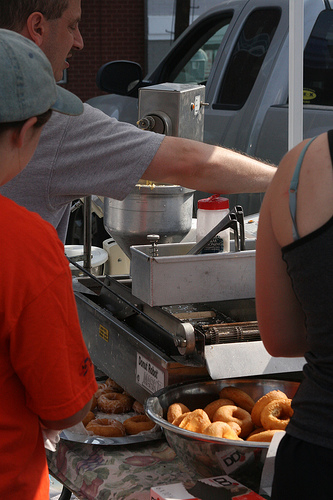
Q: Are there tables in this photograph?
A: Yes, there is a table.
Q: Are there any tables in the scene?
A: Yes, there is a table.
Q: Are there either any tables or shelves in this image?
A: Yes, there is a table.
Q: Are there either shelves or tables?
A: Yes, there is a table.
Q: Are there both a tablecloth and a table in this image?
A: Yes, there are both a table and a tablecloth.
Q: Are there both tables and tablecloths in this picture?
A: Yes, there are both a table and a tablecloth.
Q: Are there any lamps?
A: No, there are no lamps.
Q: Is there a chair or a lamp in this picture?
A: No, there are no lamps or chairs.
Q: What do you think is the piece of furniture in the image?
A: The piece of furniture is a table.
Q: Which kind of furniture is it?
A: The piece of furniture is a table.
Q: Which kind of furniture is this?
A: This is a table.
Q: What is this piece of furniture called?
A: This is a table.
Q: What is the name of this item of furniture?
A: This is a table.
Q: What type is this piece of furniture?
A: This is a table.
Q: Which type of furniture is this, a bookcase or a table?
A: This is a table.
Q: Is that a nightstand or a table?
A: That is a table.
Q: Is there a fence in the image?
A: No, there are no fences.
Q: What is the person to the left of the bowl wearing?
A: The person is wearing a shirt.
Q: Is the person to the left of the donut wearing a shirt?
A: Yes, the person is wearing a shirt.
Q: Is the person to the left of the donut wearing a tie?
A: No, the person is wearing a shirt.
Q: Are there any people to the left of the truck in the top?
A: Yes, there is a person to the left of the truck.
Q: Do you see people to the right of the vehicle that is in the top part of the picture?
A: No, the person is to the left of the truck.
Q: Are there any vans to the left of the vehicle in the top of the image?
A: No, there is a person to the left of the truck.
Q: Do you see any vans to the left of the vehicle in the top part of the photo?
A: No, there is a person to the left of the truck.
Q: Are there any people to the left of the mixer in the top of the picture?
A: Yes, there is a person to the left of the mixer.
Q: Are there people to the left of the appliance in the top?
A: Yes, there is a person to the left of the mixer.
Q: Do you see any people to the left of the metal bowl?
A: Yes, there is a person to the left of the bowl.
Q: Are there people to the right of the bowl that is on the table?
A: No, the person is to the left of the bowl.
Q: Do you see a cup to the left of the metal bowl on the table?
A: No, there is a person to the left of the bowl.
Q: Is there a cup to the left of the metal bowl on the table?
A: No, there is a person to the left of the bowl.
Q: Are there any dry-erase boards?
A: No, there are no dry-erase boards.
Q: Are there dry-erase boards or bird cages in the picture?
A: No, there are no dry-erase boards or bird cages.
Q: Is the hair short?
A: Yes, the hair is short.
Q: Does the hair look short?
A: Yes, the hair is short.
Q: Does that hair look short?
A: Yes, the hair is short.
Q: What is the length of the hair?
A: The hair is short.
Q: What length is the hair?
A: The hair is short.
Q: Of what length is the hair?
A: The hair is short.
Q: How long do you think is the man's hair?
A: The hair is short.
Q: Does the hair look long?
A: No, the hair is short.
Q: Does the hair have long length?
A: No, the hair is short.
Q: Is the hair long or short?
A: The hair is short.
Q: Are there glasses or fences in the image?
A: No, there are no fences or glasses.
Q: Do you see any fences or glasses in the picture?
A: No, there are no fences or glasses.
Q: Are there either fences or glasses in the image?
A: No, there are no fences or glasses.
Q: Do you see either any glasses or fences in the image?
A: No, there are no fences or glasses.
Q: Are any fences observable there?
A: No, there are no fences.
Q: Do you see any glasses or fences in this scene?
A: No, there are no fences or glasses.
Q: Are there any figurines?
A: No, there are no figurines.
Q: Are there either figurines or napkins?
A: No, there are no figurines or napkins.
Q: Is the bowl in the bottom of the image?
A: Yes, the bowl is in the bottom of the image.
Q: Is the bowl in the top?
A: No, the bowl is in the bottom of the image.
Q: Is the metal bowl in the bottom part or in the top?
A: The bowl is in the bottom of the image.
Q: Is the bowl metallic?
A: Yes, the bowl is metallic.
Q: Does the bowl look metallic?
A: Yes, the bowl is metallic.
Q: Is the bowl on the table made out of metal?
A: Yes, the bowl is made of metal.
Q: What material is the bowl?
A: The bowl is made of metal.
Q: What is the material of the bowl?
A: The bowl is made of metal.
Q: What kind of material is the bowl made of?
A: The bowl is made of metal.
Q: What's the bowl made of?
A: The bowl is made of metal.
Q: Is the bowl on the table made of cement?
A: No, the bowl is made of metal.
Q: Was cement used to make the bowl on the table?
A: No, the bowl is made of metal.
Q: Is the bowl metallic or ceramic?
A: The bowl is metallic.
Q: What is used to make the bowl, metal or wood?
A: The bowl is made of metal.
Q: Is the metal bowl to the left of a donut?
A: No, the bowl is to the right of a donut.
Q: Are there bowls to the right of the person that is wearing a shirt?
A: Yes, there is a bowl to the right of the person.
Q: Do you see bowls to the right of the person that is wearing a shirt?
A: Yes, there is a bowl to the right of the person.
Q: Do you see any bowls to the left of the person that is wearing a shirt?
A: No, the bowl is to the right of the person.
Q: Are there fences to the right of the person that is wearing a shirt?
A: No, there is a bowl to the right of the person.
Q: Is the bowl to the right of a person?
A: Yes, the bowl is to the right of a person.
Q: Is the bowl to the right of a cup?
A: No, the bowl is to the right of a person.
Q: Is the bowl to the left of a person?
A: No, the bowl is to the right of a person.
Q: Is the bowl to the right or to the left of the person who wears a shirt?
A: The bowl is to the right of the person.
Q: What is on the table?
A: The bowl is on the table.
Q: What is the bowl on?
A: The bowl is on the table.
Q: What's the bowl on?
A: The bowl is on the table.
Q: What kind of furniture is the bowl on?
A: The bowl is on the table.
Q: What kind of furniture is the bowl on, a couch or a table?
A: The bowl is on a table.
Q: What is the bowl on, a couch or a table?
A: The bowl is on a table.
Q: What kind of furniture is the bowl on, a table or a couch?
A: The bowl is on a table.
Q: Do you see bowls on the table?
A: Yes, there is a bowl on the table.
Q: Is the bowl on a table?
A: Yes, the bowl is on a table.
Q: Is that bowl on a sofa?
A: No, the bowl is on a table.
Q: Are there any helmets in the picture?
A: No, there are no helmets.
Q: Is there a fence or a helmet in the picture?
A: No, there are no helmets or fences.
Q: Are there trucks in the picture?
A: Yes, there is a truck.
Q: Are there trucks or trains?
A: Yes, there is a truck.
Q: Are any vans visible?
A: No, there are no vans.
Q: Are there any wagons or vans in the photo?
A: No, there are no vans or wagons.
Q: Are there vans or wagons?
A: No, there are no vans or wagons.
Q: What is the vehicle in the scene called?
A: The vehicle is a truck.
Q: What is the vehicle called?
A: The vehicle is a truck.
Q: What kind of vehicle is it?
A: The vehicle is a truck.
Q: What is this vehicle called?
A: This is a truck.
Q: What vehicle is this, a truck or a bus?
A: This is a truck.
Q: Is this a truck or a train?
A: This is a truck.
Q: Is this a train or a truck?
A: This is a truck.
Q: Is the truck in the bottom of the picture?
A: No, the truck is in the top of the image.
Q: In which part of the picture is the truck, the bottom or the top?
A: The truck is in the top of the image.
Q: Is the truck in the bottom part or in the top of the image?
A: The truck is in the top of the image.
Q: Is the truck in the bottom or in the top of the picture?
A: The truck is in the top of the image.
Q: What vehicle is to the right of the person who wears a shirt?
A: The vehicle is a truck.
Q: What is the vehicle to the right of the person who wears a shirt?
A: The vehicle is a truck.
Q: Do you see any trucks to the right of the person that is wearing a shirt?
A: Yes, there is a truck to the right of the person.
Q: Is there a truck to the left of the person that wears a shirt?
A: No, the truck is to the right of the person.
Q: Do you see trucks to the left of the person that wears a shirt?
A: No, the truck is to the right of the person.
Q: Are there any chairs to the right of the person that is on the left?
A: No, there is a truck to the right of the person.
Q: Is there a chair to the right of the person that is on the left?
A: No, there is a truck to the right of the person.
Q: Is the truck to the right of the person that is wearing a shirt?
A: Yes, the truck is to the right of the person.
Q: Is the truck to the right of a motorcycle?
A: No, the truck is to the right of the person.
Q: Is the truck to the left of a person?
A: No, the truck is to the right of a person.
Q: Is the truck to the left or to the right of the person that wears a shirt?
A: The truck is to the right of the person.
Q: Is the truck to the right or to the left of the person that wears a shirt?
A: The truck is to the right of the person.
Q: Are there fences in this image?
A: No, there are no fences.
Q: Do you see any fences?
A: No, there are no fences.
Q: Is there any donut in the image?
A: Yes, there is a donut.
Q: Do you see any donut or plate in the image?
A: Yes, there is a donut.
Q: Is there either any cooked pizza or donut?
A: Yes, there is a cooked donut.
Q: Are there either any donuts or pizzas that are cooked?
A: Yes, the donut is cooked.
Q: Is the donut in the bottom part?
A: Yes, the donut is in the bottom of the image.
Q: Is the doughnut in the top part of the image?
A: No, the doughnut is in the bottom of the image.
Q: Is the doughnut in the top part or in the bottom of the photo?
A: The doughnut is in the bottom of the image.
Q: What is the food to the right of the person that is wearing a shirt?
A: The food is a donut.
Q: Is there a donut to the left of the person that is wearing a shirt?
A: No, the donut is to the right of the person.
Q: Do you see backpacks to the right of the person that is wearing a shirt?
A: No, there is a donut to the right of the person.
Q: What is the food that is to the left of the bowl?
A: The food is a donut.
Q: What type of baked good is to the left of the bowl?
A: The food is a donut.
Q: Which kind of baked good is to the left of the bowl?
A: The food is a donut.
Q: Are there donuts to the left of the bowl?
A: Yes, there is a donut to the left of the bowl.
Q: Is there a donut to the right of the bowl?
A: No, the donut is to the left of the bowl.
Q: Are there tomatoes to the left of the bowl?
A: No, there is a donut to the left of the bowl.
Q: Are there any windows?
A: Yes, there is a window.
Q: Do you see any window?
A: Yes, there is a window.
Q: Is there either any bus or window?
A: Yes, there is a window.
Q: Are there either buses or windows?
A: Yes, there is a window.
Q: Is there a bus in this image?
A: No, there are no buses.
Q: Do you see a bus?
A: No, there are no buses.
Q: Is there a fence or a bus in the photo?
A: No, there are no buses or fences.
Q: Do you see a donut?
A: Yes, there is a donut.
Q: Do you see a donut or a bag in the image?
A: Yes, there is a donut.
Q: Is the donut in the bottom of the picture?
A: Yes, the donut is in the bottom of the image.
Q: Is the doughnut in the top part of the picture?
A: No, the doughnut is in the bottom of the image.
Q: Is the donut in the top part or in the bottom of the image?
A: The donut is in the bottom of the image.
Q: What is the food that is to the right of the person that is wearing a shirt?
A: The food is a donut.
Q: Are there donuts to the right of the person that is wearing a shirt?
A: Yes, there is a donut to the right of the person.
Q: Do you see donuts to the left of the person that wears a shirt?
A: No, the donut is to the right of the person.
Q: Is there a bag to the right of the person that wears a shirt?
A: No, there is a donut to the right of the person.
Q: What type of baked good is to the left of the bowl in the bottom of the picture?
A: The food is a donut.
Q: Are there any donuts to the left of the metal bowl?
A: Yes, there is a donut to the left of the bowl.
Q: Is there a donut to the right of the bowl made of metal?
A: No, the donut is to the left of the bowl.